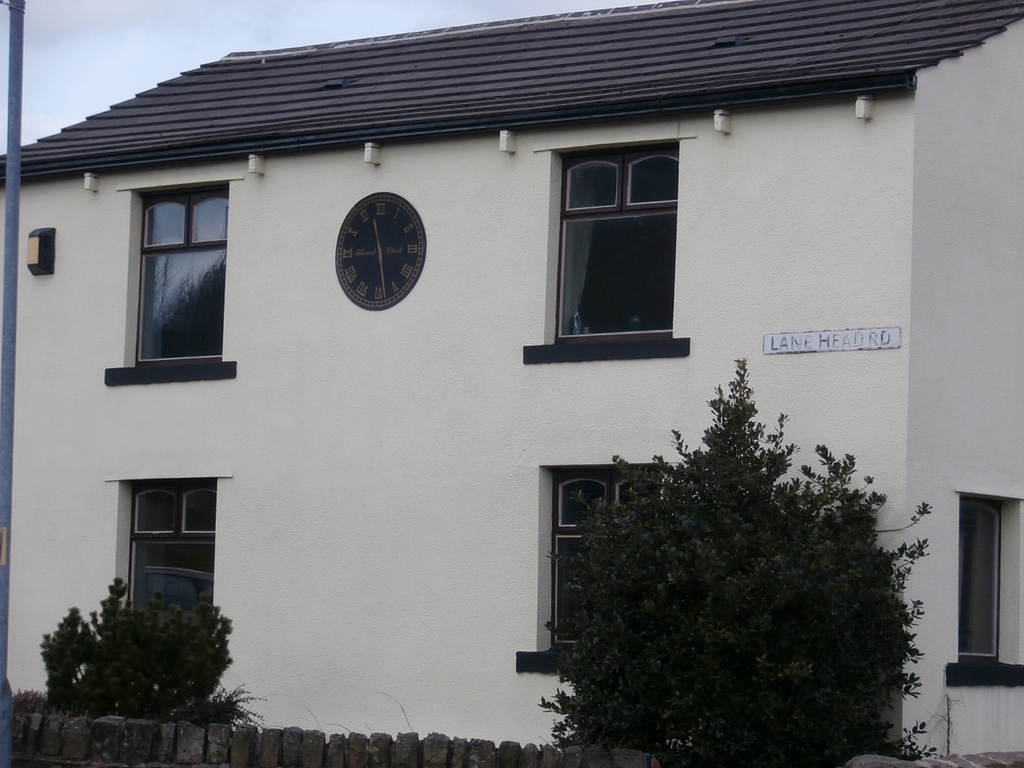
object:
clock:
[334, 190, 427, 311]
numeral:
[367, 188, 394, 218]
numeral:
[392, 219, 416, 236]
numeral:
[400, 237, 420, 254]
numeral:
[397, 256, 417, 283]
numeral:
[370, 285, 394, 304]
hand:
[370, 214, 386, 249]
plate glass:
[566, 152, 627, 204]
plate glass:
[629, 152, 675, 204]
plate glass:
[142, 198, 188, 243]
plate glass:
[187, 198, 230, 243]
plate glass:
[135, 481, 174, 535]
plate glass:
[176, 481, 214, 535]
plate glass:
[555, 475, 598, 527]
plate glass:
[610, 475, 649, 527]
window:
[106, 470, 215, 557]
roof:
[3, 4, 1022, 184]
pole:
[5, 1, 29, 765]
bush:
[555, 360, 930, 765]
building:
[2, 1, 1024, 754]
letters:
[759, 325, 902, 358]